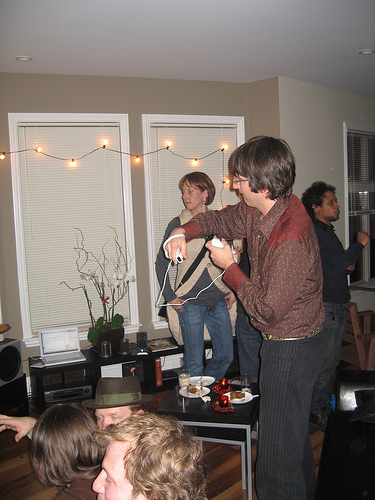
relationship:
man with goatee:
[305, 166, 368, 379] [327, 205, 349, 233]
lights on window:
[21, 99, 334, 127] [30, 112, 249, 325]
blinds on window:
[19, 116, 159, 323] [30, 112, 249, 325]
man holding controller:
[165, 134, 329, 499] [188, 229, 235, 272]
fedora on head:
[81, 376, 156, 409] [86, 355, 173, 469]